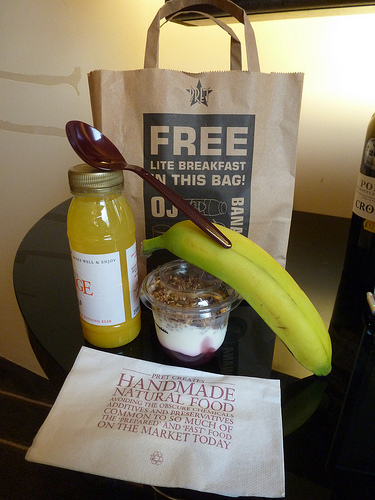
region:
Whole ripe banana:
[140, 211, 354, 379]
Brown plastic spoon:
[60, 98, 234, 250]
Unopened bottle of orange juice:
[48, 153, 151, 361]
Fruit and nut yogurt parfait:
[135, 250, 249, 368]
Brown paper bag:
[73, 7, 316, 286]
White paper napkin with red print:
[19, 341, 293, 497]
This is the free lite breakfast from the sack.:
[9, 38, 366, 492]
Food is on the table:
[7, 181, 373, 452]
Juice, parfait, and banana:
[55, 158, 339, 379]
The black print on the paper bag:
[134, 73, 269, 299]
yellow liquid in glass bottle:
[83, 203, 127, 232]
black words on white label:
[81, 251, 123, 267]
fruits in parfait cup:
[192, 333, 225, 363]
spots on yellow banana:
[268, 308, 294, 341]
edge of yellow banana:
[313, 358, 334, 381]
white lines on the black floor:
[7, 382, 31, 465]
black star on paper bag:
[169, 73, 230, 104]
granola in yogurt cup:
[158, 270, 226, 319]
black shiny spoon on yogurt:
[40, 108, 137, 179]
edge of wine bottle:
[331, 152, 370, 242]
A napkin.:
[33, 339, 296, 496]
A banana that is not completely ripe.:
[158, 210, 344, 377]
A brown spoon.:
[51, 107, 250, 249]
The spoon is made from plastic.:
[56, 105, 244, 257]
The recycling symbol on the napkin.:
[139, 444, 163, 467]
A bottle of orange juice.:
[55, 165, 148, 349]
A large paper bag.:
[86, 3, 313, 290]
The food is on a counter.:
[30, 184, 362, 450]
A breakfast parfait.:
[132, 246, 237, 366]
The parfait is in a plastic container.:
[136, 258, 251, 375]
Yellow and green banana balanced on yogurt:
[157, 216, 338, 377]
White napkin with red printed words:
[48, 336, 264, 498]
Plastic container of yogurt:
[144, 261, 243, 369]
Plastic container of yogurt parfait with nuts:
[144, 258, 237, 378]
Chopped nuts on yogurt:
[145, 271, 227, 341]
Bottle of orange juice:
[55, 148, 157, 360]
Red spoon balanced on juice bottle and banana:
[59, 113, 248, 254]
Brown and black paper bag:
[110, 51, 313, 243]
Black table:
[289, 204, 355, 354]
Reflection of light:
[203, 12, 370, 95]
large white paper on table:
[32, 348, 358, 498]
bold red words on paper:
[103, 359, 235, 471]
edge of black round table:
[2, 274, 56, 355]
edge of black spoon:
[152, 179, 235, 254]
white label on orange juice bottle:
[62, 222, 149, 334]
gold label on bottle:
[55, 156, 127, 203]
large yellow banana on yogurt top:
[149, 219, 349, 356]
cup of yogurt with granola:
[138, 266, 243, 358]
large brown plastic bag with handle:
[81, 0, 355, 184]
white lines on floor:
[15, 384, 42, 460]